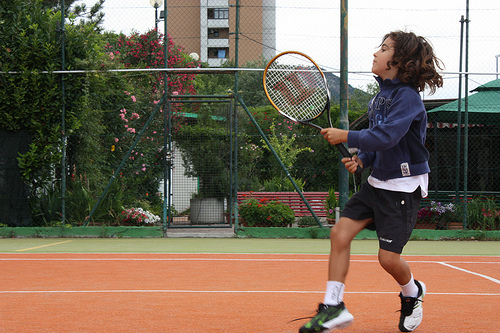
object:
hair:
[378, 29, 446, 96]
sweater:
[348, 94, 452, 188]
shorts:
[339, 180, 422, 254]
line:
[45, 252, 385, 304]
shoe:
[397, 279, 428, 332]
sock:
[316, 270, 348, 315]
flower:
[111, 91, 179, 174]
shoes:
[298, 301, 355, 333]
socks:
[315, 270, 417, 303]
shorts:
[338, 155, 428, 258]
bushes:
[18, 173, 43, 229]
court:
[0, 238, 500, 333]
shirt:
[368, 171, 430, 198]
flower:
[111, 48, 179, 91]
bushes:
[47, 73, 93, 110]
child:
[298, 30, 445, 333]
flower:
[117, 207, 160, 223]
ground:
[0, 237, 500, 293]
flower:
[111, 207, 160, 227]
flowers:
[238, 191, 296, 228]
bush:
[236, 196, 296, 227]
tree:
[64, 34, 171, 222]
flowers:
[278, 117, 300, 136]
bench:
[238, 192, 340, 228]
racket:
[263, 51, 367, 178]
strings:
[264, 52, 324, 121]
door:
[162, 101, 234, 229]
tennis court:
[0, 232, 500, 329]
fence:
[0, 11, 500, 231]